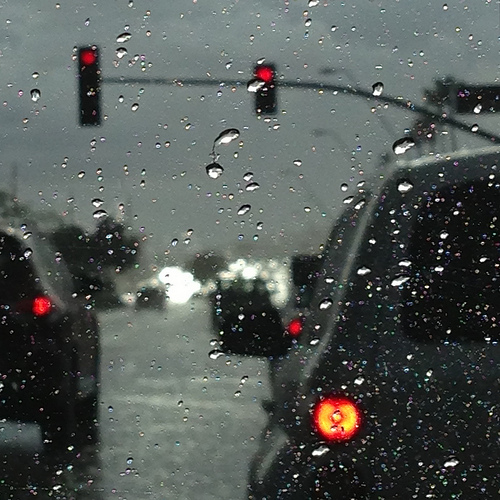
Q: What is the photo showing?
A: It is showing a highway.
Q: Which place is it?
A: It is a highway.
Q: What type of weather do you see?
A: It is rainy.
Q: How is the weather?
A: It is rainy.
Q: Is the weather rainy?
A: Yes, it is rainy.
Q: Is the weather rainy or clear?
A: It is rainy.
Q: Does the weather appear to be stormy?
A: No, it is rainy.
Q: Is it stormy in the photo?
A: No, it is rainy.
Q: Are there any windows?
A: Yes, there is a window.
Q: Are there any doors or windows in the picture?
A: Yes, there is a window.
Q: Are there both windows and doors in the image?
A: No, there is a window but no doors.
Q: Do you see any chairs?
A: No, there are no chairs.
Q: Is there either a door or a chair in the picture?
A: No, there are no chairs or doors.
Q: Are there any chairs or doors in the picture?
A: No, there are no chairs or doors.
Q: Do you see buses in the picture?
A: No, there are no buses.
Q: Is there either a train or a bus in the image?
A: No, there are no buses or trains.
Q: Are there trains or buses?
A: No, there are no buses or trains.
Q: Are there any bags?
A: No, there are no bags.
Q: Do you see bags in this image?
A: No, there are no bags.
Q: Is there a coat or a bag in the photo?
A: No, there are no bags or coats.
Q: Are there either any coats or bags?
A: No, there are no bags or coats.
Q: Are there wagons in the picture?
A: No, there are no wagons.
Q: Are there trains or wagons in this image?
A: No, there are no wagons or trains.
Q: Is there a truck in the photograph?
A: No, there are no trucks.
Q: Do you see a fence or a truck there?
A: No, there are no trucks or fences.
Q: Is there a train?
A: No, there are no trains.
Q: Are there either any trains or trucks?
A: No, there are no trains or trucks.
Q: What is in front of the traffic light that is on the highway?
A: The car is in front of the traffic light.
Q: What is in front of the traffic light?
A: The car is in front of the traffic light.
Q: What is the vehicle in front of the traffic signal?
A: The vehicle is a car.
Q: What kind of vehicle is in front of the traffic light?
A: The vehicle is a car.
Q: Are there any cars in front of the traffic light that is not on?
A: Yes, there is a car in front of the traffic light.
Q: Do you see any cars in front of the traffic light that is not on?
A: Yes, there is a car in front of the traffic light.